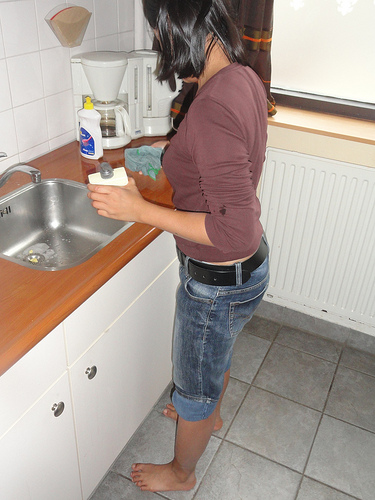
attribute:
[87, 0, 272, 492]
woman — barefoot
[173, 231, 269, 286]
belt — black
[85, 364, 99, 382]
knob — chrome, metal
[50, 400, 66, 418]
knob — chrome, metal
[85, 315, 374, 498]
tiled floor — grey, clean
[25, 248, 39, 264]
item — yellow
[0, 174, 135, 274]
sink — stainless steel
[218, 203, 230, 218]
stain — dark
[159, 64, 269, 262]
shirt — log sleeve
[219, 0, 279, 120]
curtains — orange, red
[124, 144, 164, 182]
rag — green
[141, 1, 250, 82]
hair — short, black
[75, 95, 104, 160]
bottle — white, dishsoap, soap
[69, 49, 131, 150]
coffee maker — white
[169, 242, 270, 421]
jeans — blue, rolled, rolled up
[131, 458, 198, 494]
left foot — bare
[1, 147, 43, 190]
faucet — stainless steel, metal, silver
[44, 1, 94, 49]
coffee filter holder — hanging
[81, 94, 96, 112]
lid — yellow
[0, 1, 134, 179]
wall — tiled, white